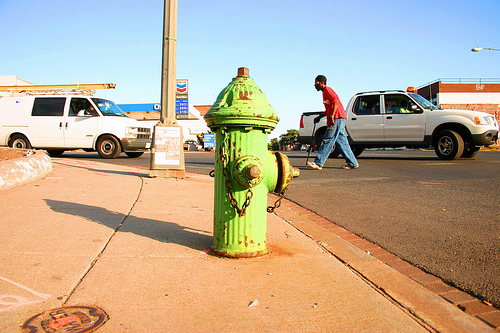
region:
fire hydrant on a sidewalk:
[190, 59, 308, 276]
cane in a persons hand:
[298, 110, 322, 172]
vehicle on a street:
[0, 70, 155, 165]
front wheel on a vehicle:
[90, 129, 127, 164]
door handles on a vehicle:
[56, 119, 71, 131]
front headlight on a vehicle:
[121, 123, 140, 143]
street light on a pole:
[463, 37, 489, 58]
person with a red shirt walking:
[291, 62, 372, 178]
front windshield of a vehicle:
[88, 95, 132, 123]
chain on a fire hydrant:
[261, 180, 293, 219]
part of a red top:
[334, 100, 346, 115]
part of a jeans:
[333, 147, 350, 156]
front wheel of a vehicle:
[97, 131, 121, 157]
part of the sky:
[348, 7, 420, 74]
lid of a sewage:
[21, 302, 106, 331]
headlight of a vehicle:
[123, 125, 140, 137]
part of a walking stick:
[306, 122, 319, 162]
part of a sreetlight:
[466, 43, 487, 65]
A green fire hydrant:
[191, 65, 308, 264]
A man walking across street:
[298, 62, 358, 179]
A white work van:
[3, 75, 152, 165]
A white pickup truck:
[299, 78, 496, 155]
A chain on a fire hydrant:
[219, 165, 256, 217]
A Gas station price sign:
[175, 79, 187, 116]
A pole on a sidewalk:
[148, 0, 190, 190]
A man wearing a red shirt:
[296, 67, 360, 124]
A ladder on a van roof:
[2, 80, 123, 97]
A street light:
[467, 37, 497, 59]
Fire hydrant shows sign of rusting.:
[186, 62, 303, 262]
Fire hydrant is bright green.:
[193, 61, 305, 260]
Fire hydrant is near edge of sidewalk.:
[141, 154, 311, 287]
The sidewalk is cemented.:
[3, 161, 476, 330]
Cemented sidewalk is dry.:
[0, 150, 482, 331]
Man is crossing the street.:
[285, 71, 364, 178]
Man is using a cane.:
[300, 114, 321, 178]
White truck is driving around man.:
[290, 77, 498, 176]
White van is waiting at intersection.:
[1, 75, 157, 165]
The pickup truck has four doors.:
[285, 83, 498, 160]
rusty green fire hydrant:
[198, 58, 303, 280]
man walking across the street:
[287, 57, 367, 197]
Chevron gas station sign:
[170, 68, 205, 133]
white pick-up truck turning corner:
[296, 68, 498, 174]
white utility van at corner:
[10, 72, 147, 169]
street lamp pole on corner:
[123, 3, 202, 184]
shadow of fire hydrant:
[41, 150, 291, 280]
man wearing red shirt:
[306, 61, 359, 128]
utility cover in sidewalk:
[14, 289, 135, 330]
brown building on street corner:
[386, 48, 495, 160]